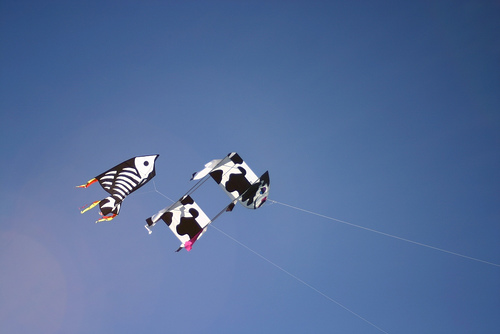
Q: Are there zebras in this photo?
A: No, there are no zebras.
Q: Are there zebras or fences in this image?
A: No, there are no zebras or fences.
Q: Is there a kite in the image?
A: Yes, there is a kite.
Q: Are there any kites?
A: Yes, there is a kite.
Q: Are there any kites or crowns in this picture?
A: Yes, there is a kite.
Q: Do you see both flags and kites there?
A: No, there is a kite but no flags.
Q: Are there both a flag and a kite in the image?
A: No, there is a kite but no flags.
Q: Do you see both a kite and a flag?
A: No, there is a kite but no flags.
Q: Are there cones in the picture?
A: No, there are no cones.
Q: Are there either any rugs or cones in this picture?
A: No, there are no cones or rugs.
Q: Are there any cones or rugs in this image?
A: No, there are no cones or rugs.